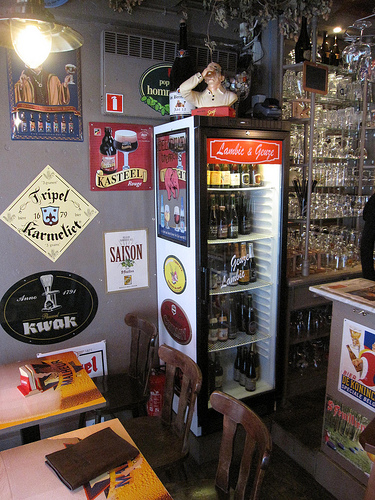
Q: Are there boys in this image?
A: No, there are no boys.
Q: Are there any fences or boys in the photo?
A: No, there are no boys or fences.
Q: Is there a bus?
A: No, there are no buses.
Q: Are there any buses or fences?
A: No, there are no buses or fences.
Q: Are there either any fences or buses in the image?
A: No, there are no buses or fences.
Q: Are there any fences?
A: No, there are no fences.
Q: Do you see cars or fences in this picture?
A: No, there are no fences or cars.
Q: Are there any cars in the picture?
A: No, there are no cars.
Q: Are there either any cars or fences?
A: No, there are no cars or fences.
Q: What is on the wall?
A: The sign is on the wall.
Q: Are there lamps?
A: Yes, there is a lamp.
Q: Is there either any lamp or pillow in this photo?
A: Yes, there is a lamp.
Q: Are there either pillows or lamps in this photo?
A: Yes, there is a lamp.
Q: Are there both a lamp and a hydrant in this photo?
A: No, there is a lamp but no fire hydrants.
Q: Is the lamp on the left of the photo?
A: Yes, the lamp is on the left of the image.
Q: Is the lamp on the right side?
A: No, the lamp is on the left of the image.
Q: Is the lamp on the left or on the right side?
A: The lamp is on the left of the image.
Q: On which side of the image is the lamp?
A: The lamp is on the left of the image.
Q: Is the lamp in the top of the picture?
A: Yes, the lamp is in the top of the image.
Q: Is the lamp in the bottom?
A: No, the lamp is in the top of the image.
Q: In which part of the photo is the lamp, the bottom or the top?
A: The lamp is in the top of the image.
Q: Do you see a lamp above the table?
A: Yes, there is a lamp above the table.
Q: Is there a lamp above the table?
A: Yes, there is a lamp above the table.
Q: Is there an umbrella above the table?
A: No, there is a lamp above the table.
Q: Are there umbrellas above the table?
A: No, there is a lamp above the table.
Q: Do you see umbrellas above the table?
A: No, there is a lamp above the table.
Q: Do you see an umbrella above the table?
A: No, there is a lamp above the table.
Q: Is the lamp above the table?
A: Yes, the lamp is above the table.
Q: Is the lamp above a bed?
A: No, the lamp is above the table.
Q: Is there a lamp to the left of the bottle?
A: Yes, there is a lamp to the left of the bottle.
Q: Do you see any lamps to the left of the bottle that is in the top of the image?
A: Yes, there is a lamp to the left of the bottle.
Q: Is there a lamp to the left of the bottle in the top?
A: Yes, there is a lamp to the left of the bottle.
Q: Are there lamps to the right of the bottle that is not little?
A: No, the lamp is to the left of the bottle.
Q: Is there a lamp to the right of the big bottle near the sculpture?
A: No, the lamp is to the left of the bottle.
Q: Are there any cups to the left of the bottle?
A: No, there is a lamp to the left of the bottle.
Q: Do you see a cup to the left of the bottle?
A: No, there is a lamp to the left of the bottle.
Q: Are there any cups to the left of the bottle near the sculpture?
A: No, there is a lamp to the left of the bottle.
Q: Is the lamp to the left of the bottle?
A: Yes, the lamp is to the left of the bottle.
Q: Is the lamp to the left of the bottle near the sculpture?
A: Yes, the lamp is to the left of the bottle.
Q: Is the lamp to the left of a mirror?
A: No, the lamp is to the left of the bottle.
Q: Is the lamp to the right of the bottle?
A: No, the lamp is to the left of the bottle.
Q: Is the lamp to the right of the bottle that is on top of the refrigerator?
A: No, the lamp is to the left of the bottle.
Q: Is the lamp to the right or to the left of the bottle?
A: The lamp is to the left of the bottle.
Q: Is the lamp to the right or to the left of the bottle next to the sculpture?
A: The lamp is to the left of the bottle.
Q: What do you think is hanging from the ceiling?
A: The lamp is hanging from the ceiling.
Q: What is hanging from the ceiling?
A: The lamp is hanging from the ceiling.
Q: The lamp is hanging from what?
A: The lamp is hanging from the ceiling.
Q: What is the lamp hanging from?
A: The lamp is hanging from the ceiling.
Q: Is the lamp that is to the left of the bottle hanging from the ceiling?
A: Yes, the lamp is hanging from the ceiling.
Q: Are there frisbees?
A: No, there are no frisbees.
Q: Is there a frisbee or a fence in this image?
A: No, there are no frisbees or fences.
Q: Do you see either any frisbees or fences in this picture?
A: No, there are no frisbees or fences.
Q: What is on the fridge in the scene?
A: The poster is on the fridge.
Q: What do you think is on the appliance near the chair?
A: The poster is on the fridge.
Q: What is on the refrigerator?
A: The poster is on the fridge.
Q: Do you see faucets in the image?
A: No, there are no faucets.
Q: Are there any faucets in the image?
A: No, there are no faucets.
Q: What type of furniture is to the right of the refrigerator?
A: The piece of furniture is a shelf.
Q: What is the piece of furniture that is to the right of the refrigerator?
A: The piece of furniture is a shelf.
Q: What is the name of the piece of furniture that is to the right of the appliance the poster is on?
A: The piece of furniture is a shelf.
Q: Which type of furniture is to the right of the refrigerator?
A: The piece of furniture is a shelf.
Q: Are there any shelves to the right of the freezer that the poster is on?
A: Yes, there is a shelf to the right of the refrigerator.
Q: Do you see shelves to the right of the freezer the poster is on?
A: Yes, there is a shelf to the right of the refrigerator.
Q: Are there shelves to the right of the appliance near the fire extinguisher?
A: Yes, there is a shelf to the right of the refrigerator.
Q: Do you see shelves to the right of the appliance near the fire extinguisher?
A: Yes, there is a shelf to the right of the refrigerator.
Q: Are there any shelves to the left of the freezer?
A: No, the shelf is to the right of the freezer.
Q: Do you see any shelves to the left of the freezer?
A: No, the shelf is to the right of the freezer.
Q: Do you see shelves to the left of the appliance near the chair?
A: No, the shelf is to the right of the freezer.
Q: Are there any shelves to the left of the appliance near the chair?
A: No, the shelf is to the right of the freezer.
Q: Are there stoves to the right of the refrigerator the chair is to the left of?
A: No, there is a shelf to the right of the freezer.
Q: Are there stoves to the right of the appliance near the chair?
A: No, there is a shelf to the right of the freezer.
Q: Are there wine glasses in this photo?
A: Yes, there is a wine glass.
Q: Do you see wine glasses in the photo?
A: Yes, there is a wine glass.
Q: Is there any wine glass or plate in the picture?
A: Yes, there is a wine glass.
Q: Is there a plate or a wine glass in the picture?
A: Yes, there is a wine glass.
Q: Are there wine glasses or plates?
A: Yes, there is a wine glass.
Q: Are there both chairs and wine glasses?
A: Yes, there are both a wine glass and a chair.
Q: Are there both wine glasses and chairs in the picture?
A: Yes, there are both a wine glass and a chair.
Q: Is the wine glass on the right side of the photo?
A: Yes, the wine glass is on the right of the image.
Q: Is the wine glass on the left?
A: No, the wine glass is on the right of the image.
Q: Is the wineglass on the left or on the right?
A: The wineglass is on the right of the image.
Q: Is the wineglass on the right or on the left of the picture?
A: The wineglass is on the right of the image.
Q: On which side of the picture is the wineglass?
A: The wineglass is on the right of the image.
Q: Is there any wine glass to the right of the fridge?
A: Yes, there is a wine glass to the right of the fridge.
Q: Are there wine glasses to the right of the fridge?
A: Yes, there is a wine glass to the right of the fridge.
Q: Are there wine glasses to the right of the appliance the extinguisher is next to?
A: Yes, there is a wine glass to the right of the fridge.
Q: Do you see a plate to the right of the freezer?
A: No, there is a wine glass to the right of the freezer.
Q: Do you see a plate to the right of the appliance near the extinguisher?
A: No, there is a wine glass to the right of the freezer.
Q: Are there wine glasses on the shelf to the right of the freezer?
A: Yes, there is a wine glass on the shelf.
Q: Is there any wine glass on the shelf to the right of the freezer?
A: Yes, there is a wine glass on the shelf.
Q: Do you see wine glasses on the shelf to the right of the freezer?
A: Yes, there is a wine glass on the shelf.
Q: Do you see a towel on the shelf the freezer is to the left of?
A: No, there is a wine glass on the shelf.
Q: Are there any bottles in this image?
A: Yes, there is a bottle.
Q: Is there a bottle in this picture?
A: Yes, there is a bottle.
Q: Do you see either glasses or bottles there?
A: Yes, there is a bottle.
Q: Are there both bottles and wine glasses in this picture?
A: Yes, there are both a bottle and a wine glass.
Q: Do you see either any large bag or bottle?
A: Yes, there is a large bottle.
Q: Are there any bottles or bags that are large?
A: Yes, the bottle is large.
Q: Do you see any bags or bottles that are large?
A: Yes, the bottle is large.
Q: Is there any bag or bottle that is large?
A: Yes, the bottle is large.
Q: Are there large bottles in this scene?
A: Yes, there is a large bottle.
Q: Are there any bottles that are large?
A: Yes, there is a bottle that is large.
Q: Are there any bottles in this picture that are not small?
A: Yes, there is a large bottle.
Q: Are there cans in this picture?
A: No, there are no cans.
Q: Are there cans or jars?
A: No, there are no cans or jars.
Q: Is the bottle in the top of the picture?
A: Yes, the bottle is in the top of the image.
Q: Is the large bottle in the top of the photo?
A: Yes, the bottle is in the top of the image.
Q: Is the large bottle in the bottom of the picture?
A: No, the bottle is in the top of the image.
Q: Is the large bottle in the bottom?
A: No, the bottle is in the top of the image.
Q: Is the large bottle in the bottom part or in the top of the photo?
A: The bottle is in the top of the image.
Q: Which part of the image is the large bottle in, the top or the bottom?
A: The bottle is in the top of the image.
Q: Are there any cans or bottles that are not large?
A: No, there is a bottle but it is large.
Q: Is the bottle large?
A: Yes, the bottle is large.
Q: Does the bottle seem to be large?
A: Yes, the bottle is large.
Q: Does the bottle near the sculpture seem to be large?
A: Yes, the bottle is large.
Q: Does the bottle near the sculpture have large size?
A: Yes, the bottle is large.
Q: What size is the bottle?
A: The bottle is large.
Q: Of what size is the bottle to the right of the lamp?
A: The bottle is large.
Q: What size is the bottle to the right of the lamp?
A: The bottle is large.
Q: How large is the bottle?
A: The bottle is large.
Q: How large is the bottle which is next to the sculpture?
A: The bottle is large.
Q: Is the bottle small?
A: No, the bottle is large.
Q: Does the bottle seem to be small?
A: No, the bottle is large.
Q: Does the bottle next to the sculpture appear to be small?
A: No, the bottle is large.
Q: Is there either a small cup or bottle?
A: No, there is a bottle but it is large.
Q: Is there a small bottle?
A: No, there is a bottle but it is large.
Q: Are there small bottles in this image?
A: No, there is a bottle but it is large.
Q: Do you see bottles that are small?
A: No, there is a bottle but it is large.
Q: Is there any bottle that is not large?
A: No, there is a bottle but it is large.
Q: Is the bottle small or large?
A: The bottle is large.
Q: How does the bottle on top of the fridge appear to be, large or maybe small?
A: The bottle is large.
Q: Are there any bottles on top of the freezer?
A: Yes, there is a bottle on top of the freezer.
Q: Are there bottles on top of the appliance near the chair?
A: Yes, there is a bottle on top of the freezer.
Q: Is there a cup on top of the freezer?
A: No, there is a bottle on top of the freezer.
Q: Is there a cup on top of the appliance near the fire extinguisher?
A: No, there is a bottle on top of the freezer.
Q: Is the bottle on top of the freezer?
A: Yes, the bottle is on top of the freezer.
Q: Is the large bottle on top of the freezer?
A: Yes, the bottle is on top of the freezer.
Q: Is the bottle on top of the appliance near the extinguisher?
A: Yes, the bottle is on top of the freezer.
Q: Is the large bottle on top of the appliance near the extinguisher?
A: Yes, the bottle is on top of the freezer.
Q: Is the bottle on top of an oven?
A: No, the bottle is on top of the freezer.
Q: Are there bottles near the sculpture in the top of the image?
A: Yes, there is a bottle near the sculpture.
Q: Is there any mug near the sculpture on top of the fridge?
A: No, there is a bottle near the sculpture.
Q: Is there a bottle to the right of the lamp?
A: Yes, there is a bottle to the right of the lamp.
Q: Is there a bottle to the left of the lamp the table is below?
A: No, the bottle is to the right of the lamp.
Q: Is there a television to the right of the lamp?
A: No, there is a bottle to the right of the lamp.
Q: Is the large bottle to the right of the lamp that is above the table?
A: Yes, the bottle is to the right of the lamp.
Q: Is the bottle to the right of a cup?
A: No, the bottle is to the right of the lamp.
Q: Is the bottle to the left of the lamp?
A: No, the bottle is to the right of the lamp.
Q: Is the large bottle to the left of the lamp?
A: No, the bottle is to the right of the lamp.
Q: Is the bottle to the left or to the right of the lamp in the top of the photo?
A: The bottle is to the right of the lamp.